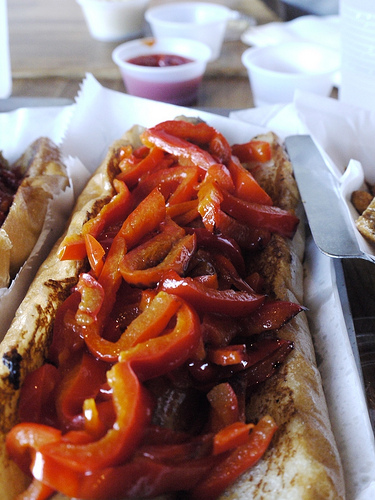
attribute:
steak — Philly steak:
[0, 135, 23, 236]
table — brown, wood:
[10, 0, 283, 120]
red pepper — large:
[72, 247, 218, 403]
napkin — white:
[241, 9, 364, 86]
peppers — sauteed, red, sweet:
[22, 92, 265, 458]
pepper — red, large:
[189, 387, 300, 464]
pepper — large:
[58, 175, 173, 311]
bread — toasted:
[251, 146, 314, 264]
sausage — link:
[150, 384, 205, 432]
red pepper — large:
[169, 273, 266, 314]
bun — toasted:
[11, 126, 141, 398]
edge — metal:
[288, 144, 344, 252]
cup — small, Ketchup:
[113, 33, 212, 103]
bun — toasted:
[252, 171, 340, 469]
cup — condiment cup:
[73, 3, 156, 41]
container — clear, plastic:
[340, 7, 374, 99]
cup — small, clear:
[184, 38, 209, 70]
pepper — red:
[130, 461, 208, 492]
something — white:
[172, 0, 207, 27]